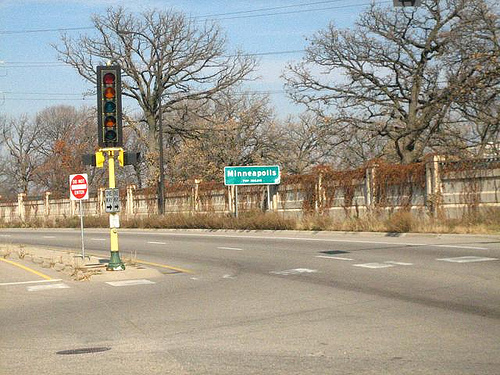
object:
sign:
[70, 175, 88, 200]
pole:
[107, 155, 117, 251]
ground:
[139, 236, 440, 269]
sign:
[124, 152, 141, 166]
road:
[0, 227, 497, 373]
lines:
[217, 246, 244, 252]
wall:
[323, 185, 367, 221]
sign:
[105, 189, 112, 212]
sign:
[113, 188, 120, 213]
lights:
[103, 72, 116, 142]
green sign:
[223, 165, 280, 186]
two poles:
[230, 187, 272, 212]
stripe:
[0, 257, 52, 280]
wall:
[439, 178, 500, 220]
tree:
[47, 0, 274, 188]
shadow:
[56, 347, 111, 355]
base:
[106, 251, 125, 271]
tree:
[276, 0, 499, 165]